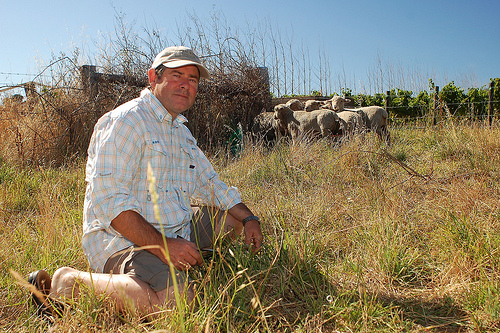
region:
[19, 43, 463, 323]
a man sitting outside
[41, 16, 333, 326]
a man kneeling outside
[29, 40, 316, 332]
a man kneeling in a field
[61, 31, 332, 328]
a man kneeling in the grass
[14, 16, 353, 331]
a man kneeling in the green grass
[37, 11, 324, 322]
a man kneeling in a green grass field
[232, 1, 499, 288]
sheep in the field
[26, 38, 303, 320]
a man wearing a hat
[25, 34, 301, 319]
a man wearing a shirt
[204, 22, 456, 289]
sheep fenced in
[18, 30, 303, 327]
a man sitting in the field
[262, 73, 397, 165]
some sheep are in the background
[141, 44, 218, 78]
the man is wearing a hat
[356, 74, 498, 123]
some plants are growing in the backgroud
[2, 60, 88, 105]
a fence is in the background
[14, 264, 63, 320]
this is the mans shoe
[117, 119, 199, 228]
the man has a striped shirt on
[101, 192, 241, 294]
the man is wearing shorts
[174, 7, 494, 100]
the sky is blue in color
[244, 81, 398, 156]
the sheep in the background are white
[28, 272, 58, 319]
Man's sandal on foot.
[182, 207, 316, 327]
Pile of unruly overgrown grass.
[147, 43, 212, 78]
Tan cap on man's head.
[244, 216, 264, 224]
Wrist watch on man's arm.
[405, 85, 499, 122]
Barbed wire fence enclosure.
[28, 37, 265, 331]
Man sitting down in field.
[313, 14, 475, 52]
Clear blue cloudless beautiful sky.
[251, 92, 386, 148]
Herd of sheep in field.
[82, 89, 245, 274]
Stripped man's cotton shirt.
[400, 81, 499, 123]
Green vegetation other side of fence.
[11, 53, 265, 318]
a man on his knees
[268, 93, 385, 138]
a group of sheep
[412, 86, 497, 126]
a barb wire fence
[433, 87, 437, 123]
a wooden fence post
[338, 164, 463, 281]
brown and green grass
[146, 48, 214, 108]
a tan hat on a mans head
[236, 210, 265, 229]
a watch on his wrist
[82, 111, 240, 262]
a plaid shit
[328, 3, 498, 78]
clear blue sky's above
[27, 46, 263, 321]
the man sitting on the grass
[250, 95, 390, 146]
the herd of sheep in the back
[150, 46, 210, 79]
the hat on the man's head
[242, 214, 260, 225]
the watch on the man's arm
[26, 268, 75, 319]
the footwear on the man's foot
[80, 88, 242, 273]
the buttoned up shirt on the man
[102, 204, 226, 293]
the shorts on the man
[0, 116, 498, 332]
the long brown and green grass on the ground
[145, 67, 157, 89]
the ear on the man's head